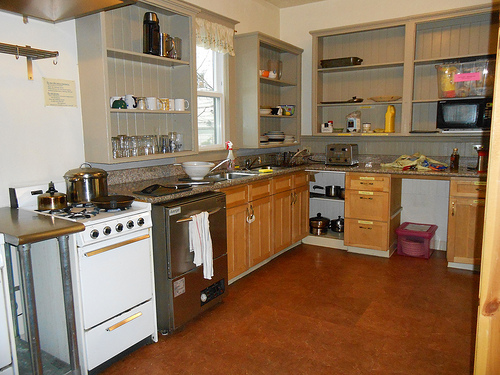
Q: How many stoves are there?
A: 1.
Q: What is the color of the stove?
A: White.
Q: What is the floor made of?
A: Tiles.